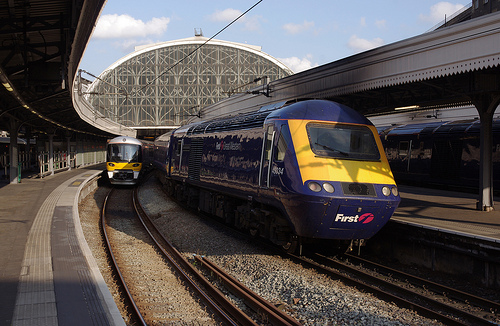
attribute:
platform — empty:
[18, 159, 148, 311]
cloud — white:
[89, 10, 174, 41]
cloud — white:
[212, 2, 257, 29]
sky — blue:
[56, 0, 476, 80]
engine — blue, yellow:
[165, 96, 405, 256]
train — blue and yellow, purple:
[153, 97, 402, 256]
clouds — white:
[87, 13, 173, 43]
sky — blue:
[87, 0, 427, 43]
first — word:
[326, 205, 370, 231]